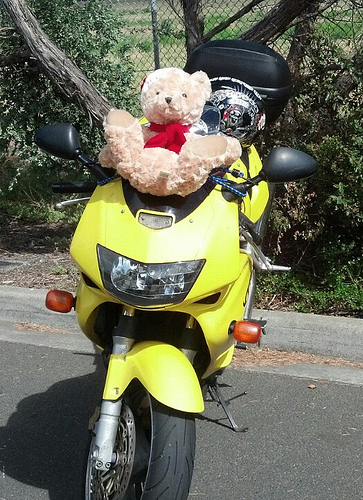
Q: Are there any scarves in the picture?
A: Yes, there is a scarf.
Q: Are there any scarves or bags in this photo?
A: Yes, there is a scarf.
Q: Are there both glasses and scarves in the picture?
A: No, there is a scarf but no glasses.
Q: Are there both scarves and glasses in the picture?
A: No, there is a scarf but no glasses.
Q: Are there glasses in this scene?
A: No, there are no glasses.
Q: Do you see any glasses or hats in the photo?
A: No, there are no glasses or hats.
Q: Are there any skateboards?
A: No, there are no skateboards.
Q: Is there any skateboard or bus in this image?
A: No, there are no skateboards or buses.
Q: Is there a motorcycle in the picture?
A: Yes, there is a motorcycle.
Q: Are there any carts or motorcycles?
A: Yes, there is a motorcycle.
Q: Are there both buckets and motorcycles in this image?
A: No, there is a motorcycle but no buckets.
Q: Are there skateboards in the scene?
A: No, there are no skateboards.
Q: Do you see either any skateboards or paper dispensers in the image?
A: No, there are no skateboards or paper dispensers.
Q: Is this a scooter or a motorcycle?
A: This is a motorcycle.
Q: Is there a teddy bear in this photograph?
A: Yes, there is a teddy bear.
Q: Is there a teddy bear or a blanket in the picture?
A: Yes, there is a teddy bear.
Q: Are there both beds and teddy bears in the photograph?
A: No, there is a teddy bear but no beds.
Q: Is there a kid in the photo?
A: No, there are no children.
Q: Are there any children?
A: No, there are no children.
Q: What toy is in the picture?
A: The toy is a teddy bear.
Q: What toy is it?
A: The toy is a teddy bear.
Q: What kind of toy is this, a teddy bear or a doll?
A: That is a teddy bear.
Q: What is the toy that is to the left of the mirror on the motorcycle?
A: The toy is a teddy bear.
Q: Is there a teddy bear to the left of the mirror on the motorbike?
A: Yes, there is a teddy bear to the left of the mirror.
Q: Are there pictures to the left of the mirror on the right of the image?
A: No, there is a teddy bear to the left of the mirror.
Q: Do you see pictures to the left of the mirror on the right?
A: No, there is a teddy bear to the left of the mirror.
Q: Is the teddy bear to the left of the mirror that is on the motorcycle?
A: Yes, the teddy bear is to the left of the mirror.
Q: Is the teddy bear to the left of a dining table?
A: No, the teddy bear is to the left of the mirror.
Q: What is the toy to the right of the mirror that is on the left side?
A: The toy is a teddy bear.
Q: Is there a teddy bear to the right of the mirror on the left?
A: Yes, there is a teddy bear to the right of the mirror.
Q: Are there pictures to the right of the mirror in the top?
A: No, there is a teddy bear to the right of the mirror.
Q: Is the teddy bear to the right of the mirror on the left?
A: Yes, the teddy bear is to the right of the mirror.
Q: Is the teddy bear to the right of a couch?
A: No, the teddy bear is to the right of the mirror.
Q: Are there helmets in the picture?
A: Yes, there is a helmet.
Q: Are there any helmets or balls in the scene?
A: Yes, there is a helmet.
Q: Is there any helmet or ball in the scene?
A: Yes, there is a helmet.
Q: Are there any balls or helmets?
A: Yes, there is a helmet.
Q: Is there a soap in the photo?
A: No, there are no soaps.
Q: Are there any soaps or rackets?
A: No, there are no soaps or rackets.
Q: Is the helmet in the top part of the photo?
A: Yes, the helmet is in the top of the image.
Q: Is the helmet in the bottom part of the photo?
A: No, the helmet is in the top of the image.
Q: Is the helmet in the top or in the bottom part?
A: The helmet is in the top of the image.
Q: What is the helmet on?
A: The helmet is on the motorbike.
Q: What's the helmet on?
A: The helmet is on the motorbike.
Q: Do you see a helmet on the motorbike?
A: Yes, there is a helmet on the motorbike.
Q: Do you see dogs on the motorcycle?
A: No, there is a helmet on the motorcycle.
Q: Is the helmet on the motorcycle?
A: Yes, the helmet is on the motorcycle.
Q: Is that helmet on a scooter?
A: No, the helmet is on the motorcycle.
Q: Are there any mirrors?
A: Yes, there is a mirror.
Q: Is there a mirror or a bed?
A: Yes, there is a mirror.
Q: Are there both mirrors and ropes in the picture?
A: No, there is a mirror but no ropes.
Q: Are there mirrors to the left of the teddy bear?
A: Yes, there is a mirror to the left of the teddy bear.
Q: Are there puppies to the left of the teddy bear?
A: No, there is a mirror to the left of the teddy bear.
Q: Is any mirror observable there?
A: Yes, there is a mirror.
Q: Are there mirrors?
A: Yes, there is a mirror.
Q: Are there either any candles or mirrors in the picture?
A: Yes, there is a mirror.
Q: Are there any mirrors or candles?
A: Yes, there is a mirror.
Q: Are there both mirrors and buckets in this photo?
A: No, there is a mirror but no buckets.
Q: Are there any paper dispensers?
A: No, there are no paper dispensers.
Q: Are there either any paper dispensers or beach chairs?
A: No, there are no paper dispensers or beach chairs.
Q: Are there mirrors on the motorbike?
A: Yes, there is a mirror on the motorbike.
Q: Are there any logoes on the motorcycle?
A: No, there is a mirror on the motorcycle.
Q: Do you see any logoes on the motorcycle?
A: No, there is a mirror on the motorcycle.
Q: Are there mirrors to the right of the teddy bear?
A: Yes, there is a mirror to the right of the teddy bear.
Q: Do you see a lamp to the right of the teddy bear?
A: No, there is a mirror to the right of the teddy bear.